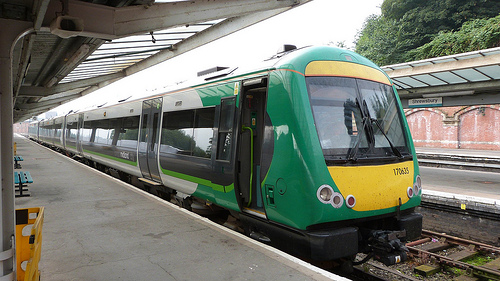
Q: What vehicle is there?
A: Train.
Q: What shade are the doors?
A: Gray.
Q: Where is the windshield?
A: Front of train.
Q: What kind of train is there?
A: Commuter.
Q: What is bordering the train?
A: Sidewalk.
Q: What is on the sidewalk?
A: Benches.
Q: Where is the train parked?
A: Train station.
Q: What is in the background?
A: Trees.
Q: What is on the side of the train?
A: Windows.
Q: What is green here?
A: Train.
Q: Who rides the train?
A: Passengers.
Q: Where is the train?
A: On the tracks.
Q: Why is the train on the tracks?
A: So it can move.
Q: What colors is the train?
A: Green and yellow.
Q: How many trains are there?
A: 1.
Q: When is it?
A: Day time.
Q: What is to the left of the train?
A: Benches.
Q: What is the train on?
A: The tracks.